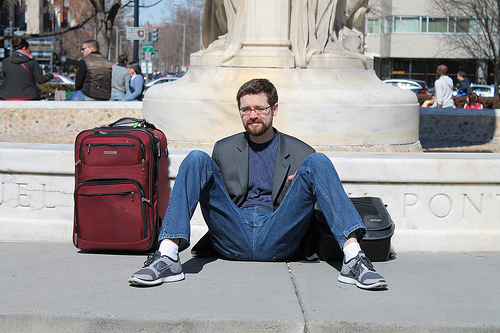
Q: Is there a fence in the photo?
A: No, there are no fences.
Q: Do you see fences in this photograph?
A: No, there are no fences.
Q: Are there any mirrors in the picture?
A: No, there are no mirrors.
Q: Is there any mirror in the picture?
A: No, there are no mirrors.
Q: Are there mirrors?
A: No, there are no mirrors.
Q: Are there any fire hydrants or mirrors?
A: No, there are no mirrors or fire hydrants.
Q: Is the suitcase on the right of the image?
A: No, the suitcase is on the left of the image.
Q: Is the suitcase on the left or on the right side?
A: The suitcase is on the left of the image.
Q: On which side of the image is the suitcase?
A: The suitcase is on the left of the image.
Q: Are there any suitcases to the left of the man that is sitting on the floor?
A: Yes, there is a suitcase to the left of the man.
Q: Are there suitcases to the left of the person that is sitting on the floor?
A: Yes, there is a suitcase to the left of the man.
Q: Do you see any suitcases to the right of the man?
A: No, the suitcase is to the left of the man.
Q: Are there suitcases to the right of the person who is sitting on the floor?
A: No, the suitcase is to the left of the man.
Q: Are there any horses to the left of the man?
A: No, there is a suitcase to the left of the man.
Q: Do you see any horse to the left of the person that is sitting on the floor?
A: No, there is a suitcase to the left of the man.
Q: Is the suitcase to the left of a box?
A: No, the suitcase is to the left of a man.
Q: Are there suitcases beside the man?
A: Yes, there is a suitcase beside the man.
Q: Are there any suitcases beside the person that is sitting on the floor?
A: Yes, there is a suitcase beside the man.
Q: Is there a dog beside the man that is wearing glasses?
A: No, there is a suitcase beside the man.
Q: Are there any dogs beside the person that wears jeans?
A: No, there is a suitcase beside the man.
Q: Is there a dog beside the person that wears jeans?
A: No, there is a suitcase beside the man.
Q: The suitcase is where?
A: The suitcase is on the floor.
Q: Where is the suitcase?
A: The suitcase is on the floor.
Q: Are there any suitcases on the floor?
A: Yes, there is a suitcase on the floor.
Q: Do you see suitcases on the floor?
A: Yes, there is a suitcase on the floor.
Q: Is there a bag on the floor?
A: No, there is a suitcase on the floor.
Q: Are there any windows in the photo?
A: Yes, there is a window.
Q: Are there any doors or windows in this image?
A: Yes, there is a window.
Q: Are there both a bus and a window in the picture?
A: No, there is a window but no buses.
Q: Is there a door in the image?
A: No, there are no doors.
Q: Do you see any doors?
A: No, there are no doors.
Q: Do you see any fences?
A: No, there are no fences.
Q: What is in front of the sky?
A: The trees are in front of the sky.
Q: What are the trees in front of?
A: The trees are in front of the sky.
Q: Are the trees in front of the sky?
A: Yes, the trees are in front of the sky.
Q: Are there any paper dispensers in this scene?
A: No, there are no paper dispensers.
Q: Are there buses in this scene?
A: No, there are no buses.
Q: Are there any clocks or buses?
A: No, there are no buses or clocks.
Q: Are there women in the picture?
A: Yes, there is a woman.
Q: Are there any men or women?
A: Yes, there is a woman.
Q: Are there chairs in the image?
A: No, there are no chairs.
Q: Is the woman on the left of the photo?
A: Yes, the woman is on the left of the image.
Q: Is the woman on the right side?
A: No, the woman is on the left of the image.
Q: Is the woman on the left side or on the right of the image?
A: The woman is on the left of the image.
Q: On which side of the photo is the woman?
A: The woman is on the left of the image.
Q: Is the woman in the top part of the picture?
A: Yes, the woman is in the top of the image.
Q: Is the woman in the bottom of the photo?
A: No, the woman is in the top of the image.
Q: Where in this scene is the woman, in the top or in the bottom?
A: The woman is in the top of the image.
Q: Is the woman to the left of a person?
A: No, the woman is to the right of a person.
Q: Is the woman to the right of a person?
A: Yes, the woman is to the right of a person.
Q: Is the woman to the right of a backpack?
A: No, the woman is to the right of a person.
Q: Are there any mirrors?
A: No, there are no mirrors.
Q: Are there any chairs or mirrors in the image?
A: No, there are no mirrors or chairs.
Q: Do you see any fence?
A: No, there are no fences.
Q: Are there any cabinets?
A: No, there are no cabinets.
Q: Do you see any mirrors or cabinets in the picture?
A: No, there are no cabinets or mirrors.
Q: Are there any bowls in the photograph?
A: No, there are no bowls.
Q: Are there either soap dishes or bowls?
A: No, there are no bowls or soap dishes.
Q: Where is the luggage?
A: The luggage is on the floor.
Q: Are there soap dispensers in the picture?
A: No, there are no soap dispensers.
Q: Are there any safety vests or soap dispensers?
A: No, there are no soap dispensers or safety vests.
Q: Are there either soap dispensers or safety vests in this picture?
A: No, there are no soap dispensers or safety vests.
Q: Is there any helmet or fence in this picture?
A: No, there are no fences or helmets.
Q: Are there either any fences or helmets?
A: No, there are no fences or helmets.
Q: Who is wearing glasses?
A: The man is wearing glasses.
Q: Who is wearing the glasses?
A: The man is wearing glasses.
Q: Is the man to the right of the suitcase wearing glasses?
A: Yes, the man is wearing glasses.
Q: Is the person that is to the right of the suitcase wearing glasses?
A: Yes, the man is wearing glasses.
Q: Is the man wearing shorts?
A: No, the man is wearing glasses.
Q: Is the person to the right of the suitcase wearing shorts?
A: No, the man is wearing glasses.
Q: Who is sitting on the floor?
A: The man is sitting on the floor.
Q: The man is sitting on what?
A: The man is sitting on the floor.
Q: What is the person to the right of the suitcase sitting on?
A: The man is sitting on the floor.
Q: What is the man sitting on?
A: The man is sitting on the floor.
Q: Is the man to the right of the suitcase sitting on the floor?
A: Yes, the man is sitting on the floor.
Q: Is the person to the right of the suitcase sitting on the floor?
A: Yes, the man is sitting on the floor.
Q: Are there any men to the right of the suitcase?
A: Yes, there is a man to the right of the suitcase.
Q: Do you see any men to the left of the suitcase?
A: No, the man is to the right of the suitcase.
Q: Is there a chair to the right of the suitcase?
A: No, there is a man to the right of the suitcase.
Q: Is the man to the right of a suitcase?
A: Yes, the man is to the right of a suitcase.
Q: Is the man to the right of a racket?
A: No, the man is to the right of a suitcase.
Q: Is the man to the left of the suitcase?
A: No, the man is to the right of the suitcase.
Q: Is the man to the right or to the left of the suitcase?
A: The man is to the right of the suitcase.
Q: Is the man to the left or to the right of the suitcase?
A: The man is to the right of the suitcase.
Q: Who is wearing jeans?
A: The man is wearing jeans.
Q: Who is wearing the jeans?
A: The man is wearing jeans.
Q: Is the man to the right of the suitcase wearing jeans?
A: Yes, the man is wearing jeans.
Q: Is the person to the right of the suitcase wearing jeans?
A: Yes, the man is wearing jeans.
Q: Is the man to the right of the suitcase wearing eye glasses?
A: No, the man is wearing jeans.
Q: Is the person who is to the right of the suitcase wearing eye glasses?
A: No, the man is wearing jeans.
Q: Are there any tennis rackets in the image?
A: No, there are no tennis rackets.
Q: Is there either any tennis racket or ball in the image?
A: No, there are no rackets or balls.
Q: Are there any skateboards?
A: No, there are no skateboards.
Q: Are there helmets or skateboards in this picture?
A: No, there are no skateboards or helmets.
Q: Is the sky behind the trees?
A: Yes, the sky is behind the trees.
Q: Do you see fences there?
A: No, there are no fences.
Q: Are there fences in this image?
A: No, there are no fences.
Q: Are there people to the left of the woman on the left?
A: Yes, there is a person to the left of the woman.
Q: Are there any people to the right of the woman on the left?
A: No, the person is to the left of the woman.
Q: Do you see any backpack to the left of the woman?
A: No, there is a person to the left of the woman.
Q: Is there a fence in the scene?
A: No, there are no fences.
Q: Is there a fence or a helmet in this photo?
A: No, there are no fences or helmets.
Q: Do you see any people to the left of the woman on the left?
A: Yes, there is a person to the left of the woman.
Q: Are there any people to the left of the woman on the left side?
A: Yes, there is a person to the left of the woman.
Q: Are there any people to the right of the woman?
A: No, the person is to the left of the woman.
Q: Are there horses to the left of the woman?
A: No, there is a person to the left of the woman.